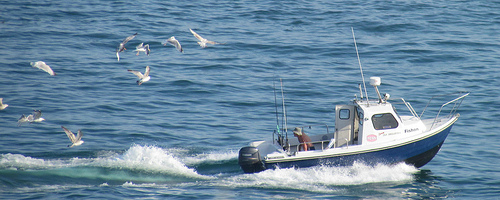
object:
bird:
[161, 36, 183, 53]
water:
[2, 2, 500, 197]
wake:
[17, 138, 235, 187]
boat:
[238, 28, 470, 173]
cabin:
[352, 99, 426, 142]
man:
[293, 127, 313, 151]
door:
[334, 105, 355, 147]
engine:
[238, 146, 264, 174]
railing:
[296, 138, 349, 156]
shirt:
[293, 133, 314, 148]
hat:
[293, 127, 303, 136]